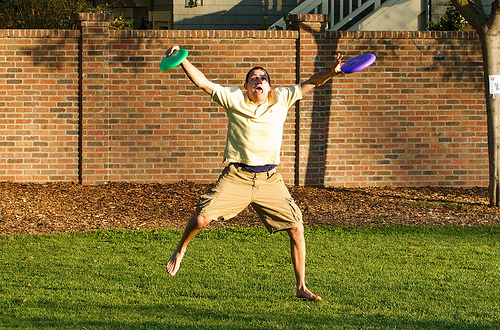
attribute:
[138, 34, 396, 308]
man — holding, playing, barefooted, jumping, catching, goofing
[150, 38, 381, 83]
discs — green, purple, blue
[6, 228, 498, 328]
grass — gren, green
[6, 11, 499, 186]
wall — bricked, shadowy, brick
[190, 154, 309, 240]
shorts — brown, tan, beige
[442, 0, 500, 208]
tree — casting, marked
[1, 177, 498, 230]
mulch — wooden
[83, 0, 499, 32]
house — white, gray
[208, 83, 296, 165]
shirt — yellow